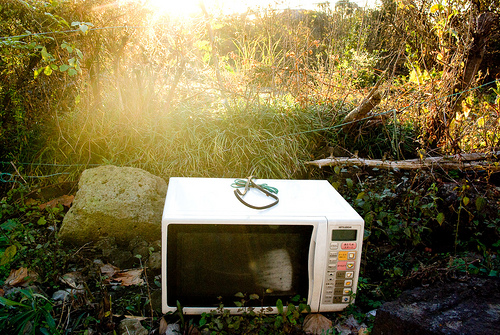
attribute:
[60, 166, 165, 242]
rock — large, grey, jagged, wide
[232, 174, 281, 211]
cord — blue, black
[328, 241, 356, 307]
buttons — pink, grey, light, white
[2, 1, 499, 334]
trees — broken, dead, green, dry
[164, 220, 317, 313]
window — black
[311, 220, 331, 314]
handle — white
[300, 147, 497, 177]
stick — large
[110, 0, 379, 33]
sun — shining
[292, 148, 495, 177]
tree — downed 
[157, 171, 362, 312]
microwave — laying, light, white